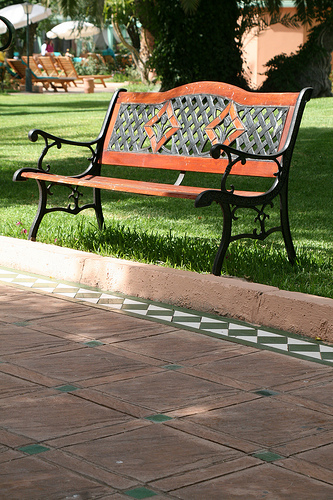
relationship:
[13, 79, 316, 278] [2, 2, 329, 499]
bench in park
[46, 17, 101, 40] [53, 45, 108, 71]
umbrella over seating area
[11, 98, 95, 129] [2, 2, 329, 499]
green space in park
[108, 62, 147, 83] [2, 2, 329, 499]
flowers are in park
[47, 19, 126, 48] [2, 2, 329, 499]
light in park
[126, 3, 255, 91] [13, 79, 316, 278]
tree behind bench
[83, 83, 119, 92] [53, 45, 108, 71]
concrete in seating area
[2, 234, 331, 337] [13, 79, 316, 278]
curb by bench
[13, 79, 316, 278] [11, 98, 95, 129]
bench in green space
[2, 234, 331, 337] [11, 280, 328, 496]
curb of sidewalk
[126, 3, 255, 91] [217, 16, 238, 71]
tree covered in ivy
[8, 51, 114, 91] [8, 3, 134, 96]
chairs are in background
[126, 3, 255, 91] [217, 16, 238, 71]
tree covered with ivy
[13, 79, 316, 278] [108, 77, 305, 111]
bench made of wood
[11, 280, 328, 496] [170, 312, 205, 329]
sidewalk has tile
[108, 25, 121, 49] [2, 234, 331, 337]
sun on curb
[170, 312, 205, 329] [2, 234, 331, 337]
tile by curb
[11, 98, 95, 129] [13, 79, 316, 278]
green space under bench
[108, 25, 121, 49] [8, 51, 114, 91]
sun on chairs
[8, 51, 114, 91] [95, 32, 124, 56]
chairs are by pool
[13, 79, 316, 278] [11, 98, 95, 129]
bench on green space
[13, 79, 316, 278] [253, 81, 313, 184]
bench made of iron and wood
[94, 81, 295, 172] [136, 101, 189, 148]
back rest has design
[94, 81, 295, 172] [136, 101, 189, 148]
back rest has a design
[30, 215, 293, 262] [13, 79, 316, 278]
legs of bench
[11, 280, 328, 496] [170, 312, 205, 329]
sidewalk features tile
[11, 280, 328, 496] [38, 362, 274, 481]
sidewalk also features stone squares